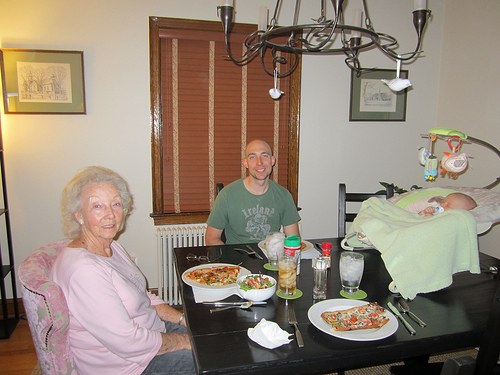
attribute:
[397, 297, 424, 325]
spoon — silver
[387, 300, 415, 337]
butter knife — silver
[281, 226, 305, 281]
bottle — plastic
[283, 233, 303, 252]
lid — green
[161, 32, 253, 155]
blinds — brown, drawn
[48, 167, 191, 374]
pink woman — wearing pink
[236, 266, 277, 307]
bowl — white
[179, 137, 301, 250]
man — bald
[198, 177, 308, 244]
shirt — green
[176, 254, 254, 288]
plate — white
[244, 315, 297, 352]
napkin — crumpled, white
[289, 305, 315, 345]
fork — silver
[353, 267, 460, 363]
utensil — knife, silver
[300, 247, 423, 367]
plate — round, white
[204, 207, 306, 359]
table — black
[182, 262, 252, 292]
plate — white, round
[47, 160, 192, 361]
woman — old 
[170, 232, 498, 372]
table — black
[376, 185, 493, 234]
baby — sleeping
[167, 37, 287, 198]
shutters — brown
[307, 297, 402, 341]
plate — white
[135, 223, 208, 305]
radiator — metal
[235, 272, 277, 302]
bowl — white 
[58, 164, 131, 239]
hair — grey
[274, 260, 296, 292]
beverage — brown